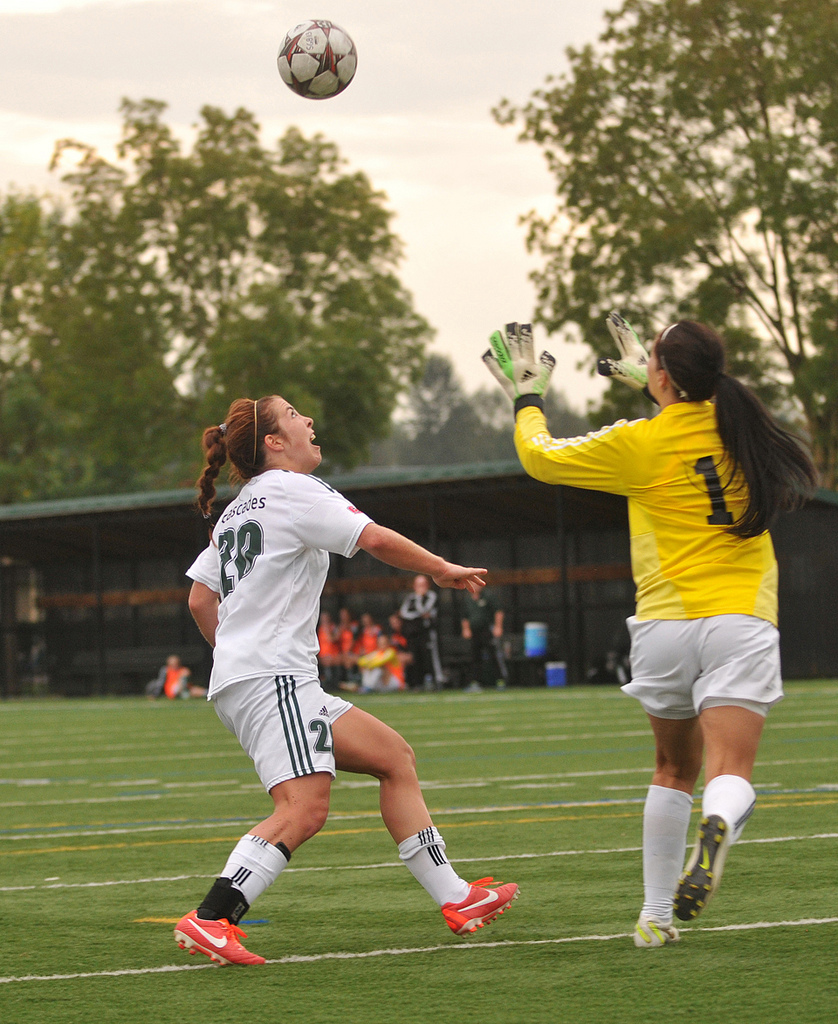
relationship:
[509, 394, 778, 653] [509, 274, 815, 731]
jersey on player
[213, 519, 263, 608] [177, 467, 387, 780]
number on uniform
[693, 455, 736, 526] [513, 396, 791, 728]
number on uniform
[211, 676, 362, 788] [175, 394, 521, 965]
shorts on woman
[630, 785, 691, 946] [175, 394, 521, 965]
sock on woman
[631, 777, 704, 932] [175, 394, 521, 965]
sock on woman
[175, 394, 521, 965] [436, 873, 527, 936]
woman wearing shoe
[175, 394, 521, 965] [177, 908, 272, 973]
woman wearing shoe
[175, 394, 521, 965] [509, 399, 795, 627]
woman wearing shirt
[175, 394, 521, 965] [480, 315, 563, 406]
woman wearing gloves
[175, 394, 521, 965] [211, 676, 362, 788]
woman wearing shorts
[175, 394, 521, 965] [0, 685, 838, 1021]
woman on soccer field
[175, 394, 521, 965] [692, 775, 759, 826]
woman wearing sock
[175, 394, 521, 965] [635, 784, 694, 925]
woman wearing sock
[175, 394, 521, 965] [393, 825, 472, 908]
woman wearing sock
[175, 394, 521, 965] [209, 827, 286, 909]
woman wearing sock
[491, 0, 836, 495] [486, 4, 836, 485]
leaves on tree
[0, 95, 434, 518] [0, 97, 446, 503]
leaves on tree